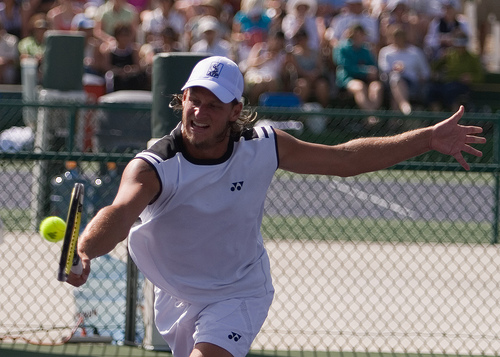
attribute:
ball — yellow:
[38, 217, 67, 242]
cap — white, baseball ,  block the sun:
[180, 54, 243, 105]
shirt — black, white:
[129, 123, 276, 301]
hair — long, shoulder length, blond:
[168, 93, 258, 135]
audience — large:
[1, 2, 500, 122]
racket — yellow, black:
[56, 181, 85, 280]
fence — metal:
[1, 153, 499, 356]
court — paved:
[2, 166, 498, 224]